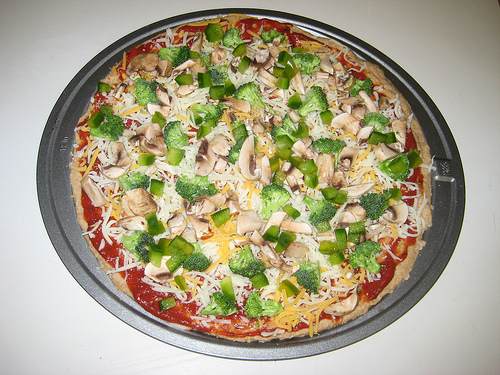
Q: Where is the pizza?
A: On the platter.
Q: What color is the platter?
A: Gray.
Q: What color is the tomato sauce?
A: Red.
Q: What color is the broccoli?
A: Green.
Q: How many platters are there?
A: One.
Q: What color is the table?
A: White.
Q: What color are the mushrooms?
A: White and brown.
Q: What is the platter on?
A: The table.